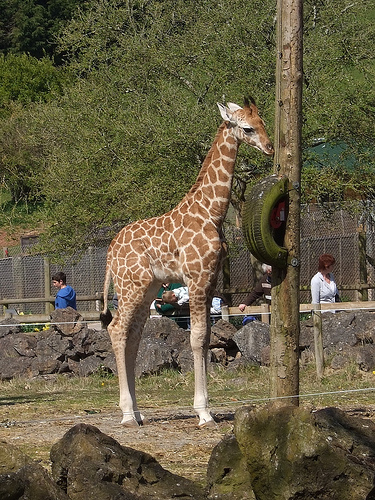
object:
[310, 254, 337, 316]
woman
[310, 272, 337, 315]
shirt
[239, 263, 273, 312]
man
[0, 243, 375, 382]
fence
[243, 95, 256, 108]
antlers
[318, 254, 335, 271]
hair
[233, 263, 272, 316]
person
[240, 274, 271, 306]
jacket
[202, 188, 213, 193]
brown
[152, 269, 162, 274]
white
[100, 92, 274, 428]
giraffe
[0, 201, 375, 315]
fence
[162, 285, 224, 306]
child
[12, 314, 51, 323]
post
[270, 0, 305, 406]
post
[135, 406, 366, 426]
shadow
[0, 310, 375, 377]
stone wall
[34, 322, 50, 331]
flowers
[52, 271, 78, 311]
man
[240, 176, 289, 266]
tire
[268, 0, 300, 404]
pole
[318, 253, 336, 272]
red hair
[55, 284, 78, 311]
hoodie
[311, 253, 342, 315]
female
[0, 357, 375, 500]
ground